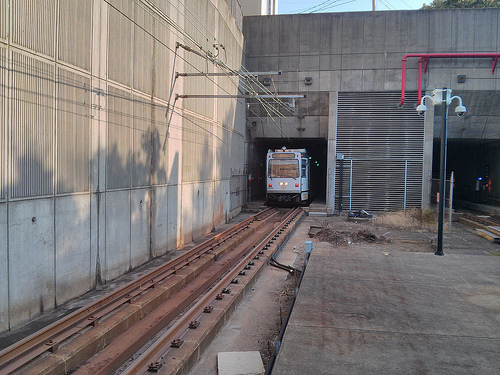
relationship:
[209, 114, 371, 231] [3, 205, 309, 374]
train on tracks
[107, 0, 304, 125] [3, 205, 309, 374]
cables above tracks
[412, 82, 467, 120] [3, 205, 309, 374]
cameras near tracks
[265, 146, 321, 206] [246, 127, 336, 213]
train coming out of tunnel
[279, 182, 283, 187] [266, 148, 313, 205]
yellow light on front of train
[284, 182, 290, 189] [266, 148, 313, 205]
yellow light on front of train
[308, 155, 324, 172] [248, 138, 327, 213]
lights in tunnel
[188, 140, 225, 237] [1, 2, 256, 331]
shadow on wall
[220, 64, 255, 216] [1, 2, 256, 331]
shadow on wall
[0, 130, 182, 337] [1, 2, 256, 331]
shadow on wall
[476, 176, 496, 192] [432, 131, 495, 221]
lights in tunnel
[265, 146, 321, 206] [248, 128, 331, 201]
train inside tunnel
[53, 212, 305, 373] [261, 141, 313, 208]
rail for train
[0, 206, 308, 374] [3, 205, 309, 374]
rail in between tracks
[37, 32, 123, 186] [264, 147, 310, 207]
wall beside train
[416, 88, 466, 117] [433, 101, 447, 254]
lights on top of pole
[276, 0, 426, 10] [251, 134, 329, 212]
sky outside tunnel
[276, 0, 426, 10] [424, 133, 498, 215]
sky outside tunnel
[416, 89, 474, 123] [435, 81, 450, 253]
lights on a pole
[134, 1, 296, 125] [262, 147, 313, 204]
electric lines for a train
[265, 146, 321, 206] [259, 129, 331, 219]
train coming from a tunnel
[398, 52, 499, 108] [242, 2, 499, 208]
pipe in wall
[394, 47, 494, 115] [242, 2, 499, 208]
pipe in wall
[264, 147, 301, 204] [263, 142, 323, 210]
front end of train